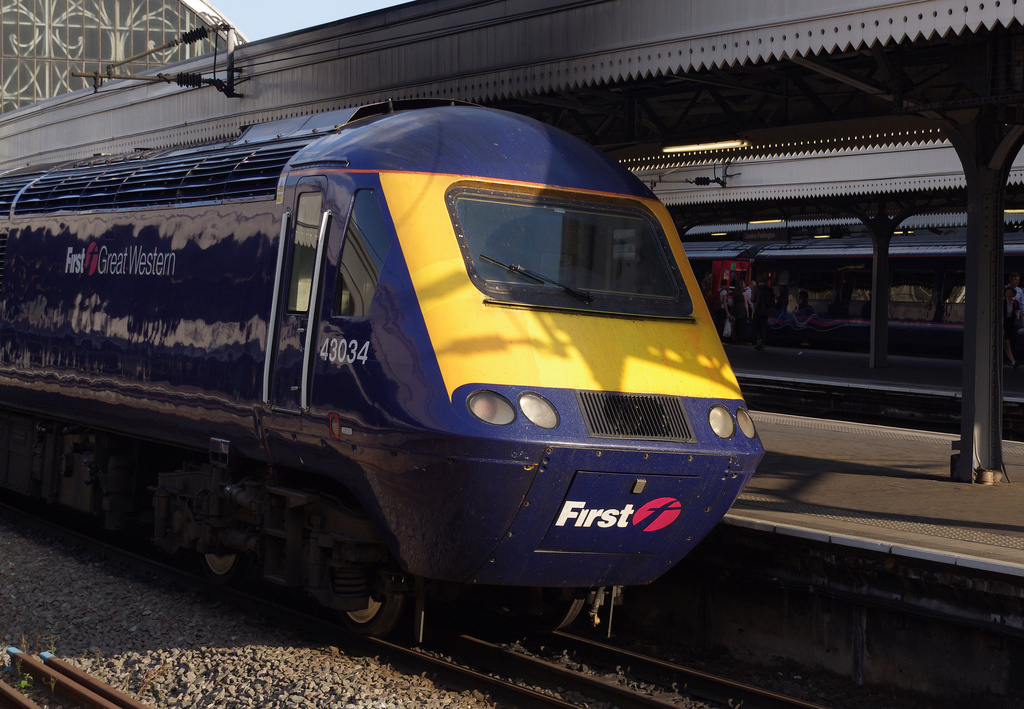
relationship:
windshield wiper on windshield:
[479, 252, 596, 303] [442, 169, 706, 325]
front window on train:
[444, 177, 699, 323] [4, 93, 767, 634]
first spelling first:
[555, 500, 634, 528] [551, 493, 636, 528]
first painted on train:
[555, 500, 634, 528] [4, 93, 767, 634]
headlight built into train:
[469, 389, 516, 425] [4, 93, 767, 634]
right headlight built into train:
[704, 402, 737, 439] [4, 93, 767, 634]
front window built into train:
[454, 197, 686, 304] [4, 93, 767, 634]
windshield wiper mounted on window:
[478, 249, 597, 302] [454, 195, 681, 299]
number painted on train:
[320, 338, 375, 365] [4, 93, 767, 634]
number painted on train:
[326, 335, 340, 361] [4, 93, 767, 634]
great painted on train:
[65, 242, 175, 275] [4, 93, 767, 634]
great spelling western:
[65, 242, 175, 275] [121, 242, 182, 279]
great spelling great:
[65, 242, 175, 275] [91, 240, 131, 279]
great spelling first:
[65, 242, 175, 275] [58, 243, 89, 276]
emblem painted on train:
[627, 485, 684, 537] [4, 93, 767, 634]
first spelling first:
[555, 500, 634, 528] [551, 493, 638, 532]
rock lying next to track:
[222, 668, 236, 681] [2, 631, 152, 705]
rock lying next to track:
[90, 655, 383, 695] [2, 631, 152, 705]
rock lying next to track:
[90, 655, 383, 695] [4, 498, 834, 704]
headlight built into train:
[512, 387, 565, 435] [4, 93, 767, 634]